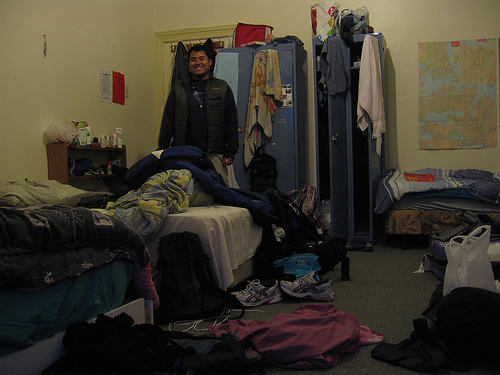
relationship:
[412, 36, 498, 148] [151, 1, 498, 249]
map on wall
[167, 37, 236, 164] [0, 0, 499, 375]
man in bedroom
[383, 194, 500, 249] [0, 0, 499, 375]
bed in bedroom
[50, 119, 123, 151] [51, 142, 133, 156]
items on shelf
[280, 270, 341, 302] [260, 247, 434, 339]
shoe on floor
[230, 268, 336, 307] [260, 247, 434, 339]
shoe on floor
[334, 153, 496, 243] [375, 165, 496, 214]
bed with comforter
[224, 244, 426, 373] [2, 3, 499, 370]
floor of bedroom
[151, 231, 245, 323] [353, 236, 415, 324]
back pack on floor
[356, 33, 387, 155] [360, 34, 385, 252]
white towel hanging over door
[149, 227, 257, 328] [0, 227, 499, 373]
back pack on floor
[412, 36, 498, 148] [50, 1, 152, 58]
map on wall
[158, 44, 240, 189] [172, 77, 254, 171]
man in vest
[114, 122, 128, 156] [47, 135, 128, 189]
tube on brown shelf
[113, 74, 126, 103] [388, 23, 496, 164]
paper on wall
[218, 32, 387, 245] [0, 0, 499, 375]
locker in bedroom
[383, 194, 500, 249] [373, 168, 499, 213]
bed with comforter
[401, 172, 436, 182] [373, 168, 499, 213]
book with comforter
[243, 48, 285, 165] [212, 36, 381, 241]
clothing on locker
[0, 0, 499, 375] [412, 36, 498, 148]
bedroom w map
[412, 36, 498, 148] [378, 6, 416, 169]
map map wall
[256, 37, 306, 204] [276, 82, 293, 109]
locker w sticker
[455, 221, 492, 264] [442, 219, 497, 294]
plastic bag w plastic bag